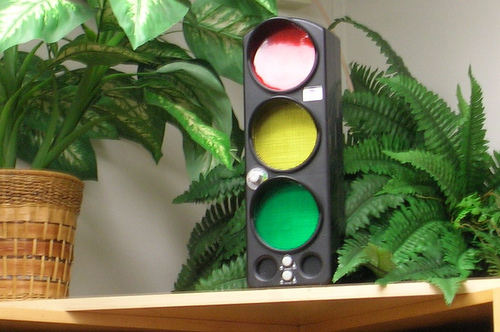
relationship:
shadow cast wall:
[84, 154, 184, 285] [83, 208, 170, 270]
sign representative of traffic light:
[244, 96, 318, 172] [239, 15, 338, 281]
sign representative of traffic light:
[250, 175, 322, 251] [239, 15, 338, 281]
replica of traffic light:
[241, 18, 341, 283] [239, 15, 338, 281]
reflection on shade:
[241, 37, 335, 101] [243, 18, 320, 89]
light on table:
[240, 15, 338, 287] [0, 275, 499, 325]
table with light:
[241, 14, 339, 289] [243, 18, 343, 281]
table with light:
[38, 268, 493, 323] [243, 18, 343, 281]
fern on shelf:
[169, 17, 496, 305] [1, 276, 498, 330]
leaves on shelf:
[2, 0, 279, 182] [1, 276, 498, 330]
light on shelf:
[240, 15, 338, 287] [1, 276, 498, 330]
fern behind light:
[169, 17, 496, 305] [240, 15, 338, 287]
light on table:
[240, 15, 338, 287] [20, 152, 435, 330]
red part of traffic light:
[248, 21, 318, 95] [234, 12, 345, 289]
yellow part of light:
[248, 103, 318, 172] [248, 95, 320, 171]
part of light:
[250, 179, 321, 248] [240, 15, 338, 287]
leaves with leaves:
[2, 0, 279, 182] [2, 0, 279, 182]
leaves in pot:
[2, 0, 279, 182] [0, 172, 93, 300]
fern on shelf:
[169, 17, 496, 305] [3, 272, 499, 324]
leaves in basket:
[2, 0, 279, 182] [1, 167, 84, 299]